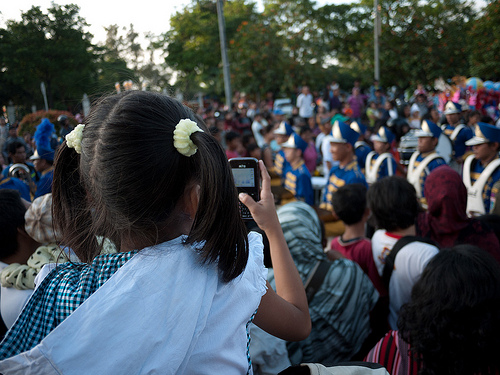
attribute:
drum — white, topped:
[312, 176, 332, 206]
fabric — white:
[5, 227, 274, 373]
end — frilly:
[242, 306, 258, 373]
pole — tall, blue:
[209, 1, 254, 107]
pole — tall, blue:
[366, 1, 391, 88]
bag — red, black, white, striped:
[365, 232, 418, 331]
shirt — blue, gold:
[320, 158, 365, 215]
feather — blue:
[33, 116, 56, 166]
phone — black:
[224, 157, 264, 222]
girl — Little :
[14, 68, 323, 373]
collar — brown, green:
[335, 234, 365, 244]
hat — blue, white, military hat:
[327, 112, 362, 147]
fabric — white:
[142, 352, 165, 359]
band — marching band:
[222, 100, 499, 220]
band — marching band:
[1, 119, 60, 208]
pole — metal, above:
[208, 1, 249, 111]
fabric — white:
[59, 242, 257, 373]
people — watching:
[19, 109, 499, 354]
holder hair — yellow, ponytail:
[155, 112, 257, 283]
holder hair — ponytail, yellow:
[48, 120, 108, 265]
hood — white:
[157, 260, 194, 333]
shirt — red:
[327, 230, 383, 278]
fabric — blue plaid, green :
[0, 250, 143, 355]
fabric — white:
[95, 287, 140, 323]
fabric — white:
[147, 289, 163, 297]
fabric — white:
[131, 318, 162, 347]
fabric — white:
[138, 295, 172, 316]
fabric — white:
[129, 279, 156, 304]